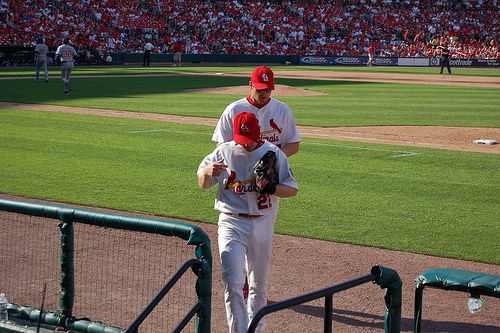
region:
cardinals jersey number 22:
[205, 117, 345, 324]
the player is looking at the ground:
[222, 101, 273, 151]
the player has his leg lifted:
[202, 223, 309, 324]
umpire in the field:
[424, 20, 471, 119]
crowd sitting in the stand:
[64, 12, 346, 43]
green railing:
[22, 193, 192, 308]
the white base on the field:
[333, 71, 495, 178]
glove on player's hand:
[240, 144, 295, 233]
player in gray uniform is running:
[44, 35, 91, 115]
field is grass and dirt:
[141, 54, 483, 204]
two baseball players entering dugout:
[192, 53, 309, 332]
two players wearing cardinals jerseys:
[188, 64, 318, 329]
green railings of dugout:
[10, 194, 490, 331]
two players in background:
[30, 26, 80, 91]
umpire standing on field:
[432, 37, 454, 67]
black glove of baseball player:
[250, 151, 283, 193]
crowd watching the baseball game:
[21, 6, 485, 66]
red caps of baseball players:
[224, 58, 276, 151]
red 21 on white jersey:
[251, 193, 281, 213]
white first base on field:
[465, 129, 496, 150]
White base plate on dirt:
[472, 135, 498, 147]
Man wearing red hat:
[214, 65, 302, 159]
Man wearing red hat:
[198, 110, 298, 332]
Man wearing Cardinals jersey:
[210, 65, 302, 155]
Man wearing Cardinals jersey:
[191, 107, 297, 332]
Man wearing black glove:
[197, 110, 300, 331]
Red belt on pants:
[227, 210, 268, 220]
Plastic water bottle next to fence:
[0, 288, 12, 320]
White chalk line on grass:
[126, 123, 422, 157]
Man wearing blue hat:
[52, 34, 79, 97]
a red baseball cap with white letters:
[251, 65, 277, 92]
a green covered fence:
[2, 190, 218, 331]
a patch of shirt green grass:
[14, 120, 180, 186]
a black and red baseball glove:
[255, 149, 280, 196]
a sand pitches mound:
[193, 81, 325, 95]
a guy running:
[55, 38, 80, 94]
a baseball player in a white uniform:
[194, 113, 297, 328]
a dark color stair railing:
[243, 265, 404, 331]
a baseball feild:
[1, 58, 497, 271]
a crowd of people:
[1, 0, 498, 62]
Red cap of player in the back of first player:
[245, 62, 280, 89]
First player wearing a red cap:
[227, 108, 263, 146]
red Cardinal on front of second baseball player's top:
[262, 114, 286, 140]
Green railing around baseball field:
[0, 195, 211, 331]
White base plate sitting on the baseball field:
[463, 121, 495, 152]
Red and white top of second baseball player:
[205, 92, 308, 142]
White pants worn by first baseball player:
[213, 210, 271, 330]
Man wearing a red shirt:
[358, 41, 373, 51]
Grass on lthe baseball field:
[0, 62, 496, 262]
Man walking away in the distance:
[49, 35, 85, 88]